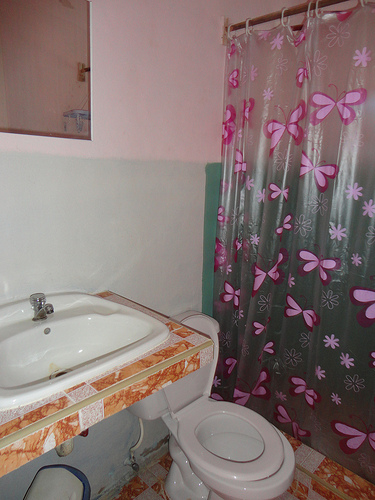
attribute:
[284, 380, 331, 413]
butterfly — pink, purple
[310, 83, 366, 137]
butterfly — pink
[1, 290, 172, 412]
sink — patterned, orange, white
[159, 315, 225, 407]
lid — up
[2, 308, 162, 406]
sink — white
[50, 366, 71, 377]
drain — in middle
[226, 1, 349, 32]
shower rod — wood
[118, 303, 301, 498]
toilet — white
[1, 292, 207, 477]
counter top — tile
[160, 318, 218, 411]
lid — up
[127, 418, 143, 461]
pipe — white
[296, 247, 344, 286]
butterfly — pink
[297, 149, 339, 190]
butterfly — pink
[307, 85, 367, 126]
butterfly — pink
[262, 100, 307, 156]
butterfly — pink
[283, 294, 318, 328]
butterfly — pink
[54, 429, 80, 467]
pipe — white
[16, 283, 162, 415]
sink — white, orange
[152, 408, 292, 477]
seat — open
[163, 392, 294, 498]
stool — white